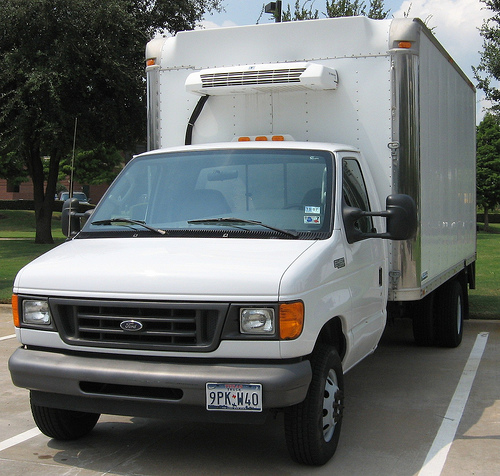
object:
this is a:
[205, 380, 261, 413]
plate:
[206, 381, 263, 413]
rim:
[321, 368, 341, 443]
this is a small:
[238, 135, 252, 141]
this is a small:
[255, 136, 267, 142]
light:
[255, 137, 269, 138]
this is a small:
[272, 136, 284, 141]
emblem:
[120, 319, 143, 331]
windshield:
[80, 149, 328, 230]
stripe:
[417, 331, 492, 475]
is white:
[439, 427, 451, 448]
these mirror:
[385, 192, 417, 240]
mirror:
[62, 198, 80, 235]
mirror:
[82, 156, 328, 236]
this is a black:
[187, 217, 297, 238]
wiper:
[185, 217, 298, 238]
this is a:
[90, 216, 168, 236]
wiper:
[91, 217, 164, 235]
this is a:
[7, 346, 315, 411]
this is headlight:
[272, 135, 284, 142]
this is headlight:
[397, 42, 412, 50]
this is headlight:
[141, 57, 155, 67]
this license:
[204, 382, 263, 411]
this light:
[241, 309, 271, 333]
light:
[23, 300, 50, 326]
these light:
[278, 302, 306, 339]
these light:
[12, 293, 23, 327]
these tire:
[434, 279, 464, 349]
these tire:
[412, 291, 434, 345]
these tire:
[30, 390, 104, 440]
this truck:
[8, 16, 477, 466]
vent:
[184, 62, 337, 98]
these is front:
[75, 149, 337, 237]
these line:
[417, 331, 491, 475]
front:
[8, 148, 336, 425]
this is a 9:
[210, 390, 216, 404]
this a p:
[216, 391, 224, 404]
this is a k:
[225, 391, 232, 405]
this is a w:
[236, 392, 244, 405]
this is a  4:
[246, 392, 252, 408]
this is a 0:
[252, 393, 259, 404]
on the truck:
[186, 62, 338, 96]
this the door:
[335, 151, 382, 330]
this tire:
[287, 353, 343, 466]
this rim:
[323, 383, 339, 440]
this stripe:
[0, 425, 42, 454]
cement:
[463, 429, 499, 475]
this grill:
[75, 304, 202, 346]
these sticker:
[303, 205, 319, 212]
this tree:
[0, 0, 229, 244]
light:
[264, 1, 280, 14]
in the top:
[263, 1, 283, 24]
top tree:
[255, 0, 394, 23]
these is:
[0, 209, 76, 302]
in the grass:
[0, 208, 65, 303]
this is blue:
[145, 1, 499, 125]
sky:
[150, 0, 498, 127]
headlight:
[236, 136, 252, 141]